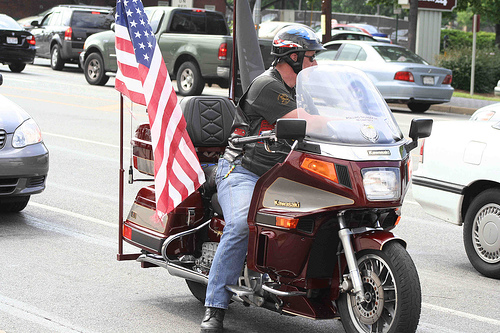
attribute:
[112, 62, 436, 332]
motorcycle — burgundy, black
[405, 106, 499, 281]
car — driving, white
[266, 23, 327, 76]
helmet — red, blue, white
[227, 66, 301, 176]
jacket — black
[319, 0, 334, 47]
post — green, metal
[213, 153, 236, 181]
key ring — rainbow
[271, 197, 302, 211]
lettering — gold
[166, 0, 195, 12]
sign — black, white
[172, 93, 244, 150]
seat back — leather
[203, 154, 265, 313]
jeans — blue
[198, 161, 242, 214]
seat — black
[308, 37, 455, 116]
car — silver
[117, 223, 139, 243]
reflector — orange